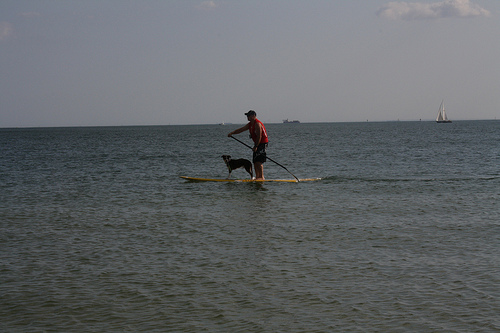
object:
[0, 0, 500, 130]
sky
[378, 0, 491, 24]
clouds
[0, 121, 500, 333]
water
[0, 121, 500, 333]
ripples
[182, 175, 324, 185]
surfboard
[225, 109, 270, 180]
man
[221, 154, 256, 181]
dog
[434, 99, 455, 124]
yacht